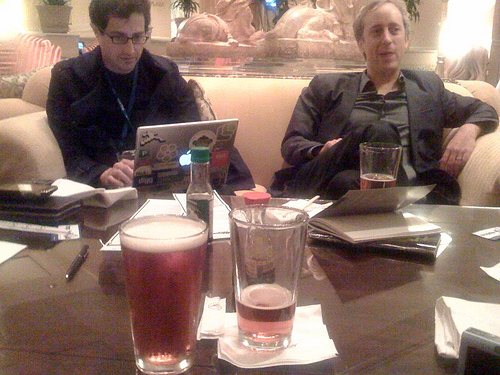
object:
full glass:
[119, 213, 209, 373]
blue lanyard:
[107, 73, 131, 143]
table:
[0, 193, 500, 375]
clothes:
[267, 69, 500, 198]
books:
[307, 183, 445, 262]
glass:
[359, 142, 403, 188]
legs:
[285, 122, 403, 194]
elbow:
[462, 98, 498, 127]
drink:
[361, 173, 396, 189]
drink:
[233, 283, 290, 338]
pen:
[65, 243, 89, 280]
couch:
[0, 64, 500, 208]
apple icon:
[178, 149, 192, 166]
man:
[46, 0, 257, 196]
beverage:
[116, 243, 203, 364]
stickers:
[138, 123, 235, 190]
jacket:
[267, 70, 500, 200]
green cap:
[191, 146, 210, 162]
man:
[264, 0, 497, 205]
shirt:
[340, 70, 414, 186]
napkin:
[197, 294, 339, 370]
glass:
[229, 203, 310, 351]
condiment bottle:
[186, 147, 213, 245]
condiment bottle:
[243, 192, 276, 284]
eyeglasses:
[99, 30, 148, 44]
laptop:
[132, 119, 239, 195]